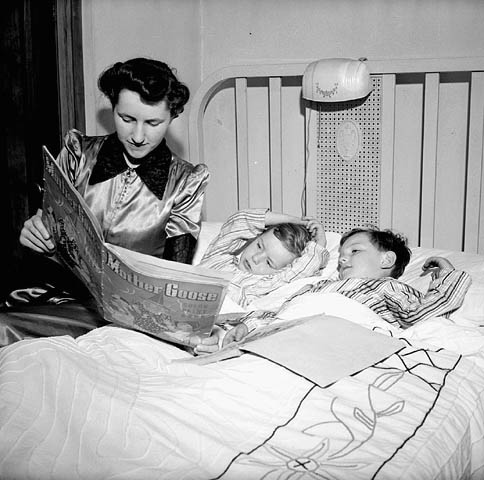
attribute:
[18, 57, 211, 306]
woman — sitting, readng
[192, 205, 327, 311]
child — relaxing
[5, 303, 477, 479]
blanket — white, black, light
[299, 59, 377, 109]
lamp — hanging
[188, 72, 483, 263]
bed — white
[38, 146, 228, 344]
book — mother goose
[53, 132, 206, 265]
dress — silk, shiny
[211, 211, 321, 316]
shirt — striped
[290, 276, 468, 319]
shirt — striped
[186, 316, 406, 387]
book — open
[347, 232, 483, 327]
pillow — white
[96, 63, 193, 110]
hair — dark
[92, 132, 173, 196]
collar — dark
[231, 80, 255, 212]
rail — white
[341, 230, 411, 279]
hair — dark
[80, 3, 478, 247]
wall — light